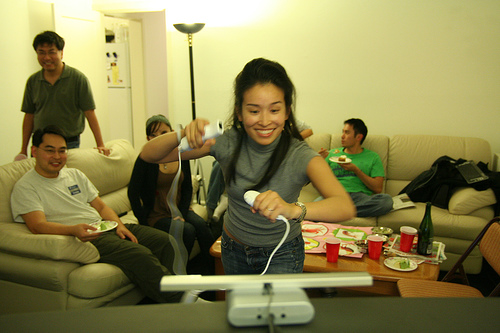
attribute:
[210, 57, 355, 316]
girl — one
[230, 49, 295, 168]
hair — black, long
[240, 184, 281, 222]
controller — white, Wii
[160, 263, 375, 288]
bar — Wii, sensor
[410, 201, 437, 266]
bottle — green, glass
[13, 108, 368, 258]
people — some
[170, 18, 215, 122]
lamp — black, floor 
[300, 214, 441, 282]
table — coffee, wooden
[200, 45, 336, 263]
woman — one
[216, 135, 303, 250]
shirt — one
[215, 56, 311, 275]
woman — one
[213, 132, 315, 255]
shirt — gray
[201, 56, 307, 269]
woman — one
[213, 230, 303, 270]
pants — blue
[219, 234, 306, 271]
pants — blue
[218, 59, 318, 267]
woman — one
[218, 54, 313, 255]
woman — one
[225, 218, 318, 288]
jeans — blue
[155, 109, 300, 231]
remotes — Wii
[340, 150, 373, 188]
shirt — green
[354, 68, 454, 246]
couch — white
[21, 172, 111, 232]
shirt — white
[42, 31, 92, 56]
hair — black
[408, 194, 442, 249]
bottle — green, colored, wine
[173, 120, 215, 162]
controller — white, wii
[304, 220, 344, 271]
cup — red, plastic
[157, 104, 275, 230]
remotes — wii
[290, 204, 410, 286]
cups — red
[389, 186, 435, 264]
bottle — green, glass